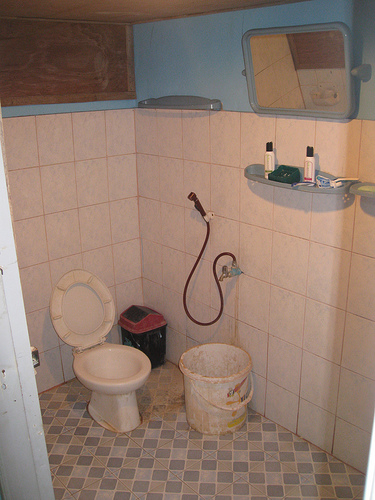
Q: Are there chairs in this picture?
A: No, there are no chairs.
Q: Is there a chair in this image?
A: No, there are no chairs.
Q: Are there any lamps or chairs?
A: No, there are no chairs or lamps.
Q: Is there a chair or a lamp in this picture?
A: No, there are no chairs or lamps.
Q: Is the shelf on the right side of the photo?
A: Yes, the shelf is on the right of the image.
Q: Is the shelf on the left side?
A: No, the shelf is on the right of the image.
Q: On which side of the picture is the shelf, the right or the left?
A: The shelf is on the right of the image.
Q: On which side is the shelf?
A: The shelf is on the right of the image.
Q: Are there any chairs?
A: No, there are no chairs.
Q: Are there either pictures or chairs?
A: No, there are no chairs or pictures.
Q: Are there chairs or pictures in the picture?
A: No, there are no chairs or pictures.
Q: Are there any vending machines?
A: No, there are no vending machines.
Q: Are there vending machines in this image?
A: No, there are no vending machines.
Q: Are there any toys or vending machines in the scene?
A: No, there are no vending machines or toys.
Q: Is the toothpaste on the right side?
A: Yes, the toothpaste is on the right of the image.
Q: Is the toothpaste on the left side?
A: No, the toothpaste is on the right of the image.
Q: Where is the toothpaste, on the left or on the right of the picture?
A: The toothpaste is on the right of the image.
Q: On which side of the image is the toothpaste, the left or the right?
A: The toothpaste is on the right of the image.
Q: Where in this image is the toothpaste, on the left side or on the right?
A: The toothpaste is on the right of the image.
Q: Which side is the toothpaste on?
A: The toothpaste is on the right of the image.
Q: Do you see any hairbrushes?
A: No, there are no hairbrushes.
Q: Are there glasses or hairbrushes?
A: No, there are no hairbrushes or glasses.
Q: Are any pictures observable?
A: No, there are no pictures.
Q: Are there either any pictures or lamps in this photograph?
A: No, there are no pictures or lamps.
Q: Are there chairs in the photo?
A: No, there are no chairs.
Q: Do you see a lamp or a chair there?
A: No, there are no chairs or lamps.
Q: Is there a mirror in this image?
A: Yes, there is a mirror.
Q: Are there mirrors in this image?
A: Yes, there is a mirror.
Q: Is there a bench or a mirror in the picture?
A: Yes, there is a mirror.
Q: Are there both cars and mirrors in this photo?
A: No, there is a mirror but no cars.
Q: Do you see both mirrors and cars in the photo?
A: No, there is a mirror but no cars.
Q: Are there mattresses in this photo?
A: No, there are no mattresses.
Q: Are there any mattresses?
A: No, there are no mattresses.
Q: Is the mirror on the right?
A: Yes, the mirror is on the right of the image.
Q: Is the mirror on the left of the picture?
A: No, the mirror is on the right of the image.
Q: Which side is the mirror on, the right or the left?
A: The mirror is on the right of the image.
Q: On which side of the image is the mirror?
A: The mirror is on the right of the image.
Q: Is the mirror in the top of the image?
A: Yes, the mirror is in the top of the image.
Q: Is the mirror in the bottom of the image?
A: No, the mirror is in the top of the image.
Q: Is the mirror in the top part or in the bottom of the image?
A: The mirror is in the top of the image.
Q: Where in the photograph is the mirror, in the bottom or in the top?
A: The mirror is in the top of the image.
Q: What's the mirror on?
A: The mirror is on the wall.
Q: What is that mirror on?
A: The mirror is on the wall.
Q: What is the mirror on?
A: The mirror is on the wall.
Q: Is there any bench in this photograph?
A: No, there are no benches.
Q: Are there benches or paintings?
A: No, there are no benches or paintings.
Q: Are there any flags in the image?
A: No, there are no flags.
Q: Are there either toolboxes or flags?
A: No, there are no flags or toolboxes.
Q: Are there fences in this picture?
A: No, there are no fences.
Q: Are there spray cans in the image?
A: No, there are no spray cans.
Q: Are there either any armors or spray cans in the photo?
A: No, there are no spray cans or armors.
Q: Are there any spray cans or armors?
A: No, there are no spray cans or armors.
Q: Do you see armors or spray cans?
A: No, there are no spray cans or armors.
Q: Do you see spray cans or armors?
A: No, there are no spray cans or armors.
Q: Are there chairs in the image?
A: No, there are no chairs.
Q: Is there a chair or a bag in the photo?
A: No, there are no chairs or bags.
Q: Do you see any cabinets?
A: No, there are no cabinets.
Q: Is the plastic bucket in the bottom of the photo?
A: Yes, the bucket is in the bottom of the image.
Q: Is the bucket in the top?
A: No, the bucket is in the bottom of the image.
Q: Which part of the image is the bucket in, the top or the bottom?
A: The bucket is in the bottom of the image.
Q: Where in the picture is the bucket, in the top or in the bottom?
A: The bucket is in the bottom of the image.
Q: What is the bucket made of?
A: The bucket is made of plastic.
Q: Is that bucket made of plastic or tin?
A: The bucket is made of plastic.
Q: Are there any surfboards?
A: No, there are no surfboards.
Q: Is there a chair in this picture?
A: No, there are no chairs.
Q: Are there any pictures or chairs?
A: No, there are no chairs or pictures.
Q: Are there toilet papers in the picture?
A: No, there are no toilet papers.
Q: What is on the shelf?
A: The toiletries are on the shelf.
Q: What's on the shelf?
A: The toiletries are on the shelf.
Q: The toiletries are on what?
A: The toiletries are on the shelf.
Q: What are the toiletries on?
A: The toiletries are on the shelf.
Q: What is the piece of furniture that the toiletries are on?
A: The piece of furniture is a shelf.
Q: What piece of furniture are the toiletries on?
A: The toiletries are on the shelf.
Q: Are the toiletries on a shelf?
A: Yes, the toiletries are on a shelf.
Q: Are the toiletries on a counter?
A: No, the toiletries are on a shelf.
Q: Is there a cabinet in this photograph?
A: No, there are no cabinets.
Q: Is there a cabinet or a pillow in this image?
A: No, there are no cabinets or pillows.